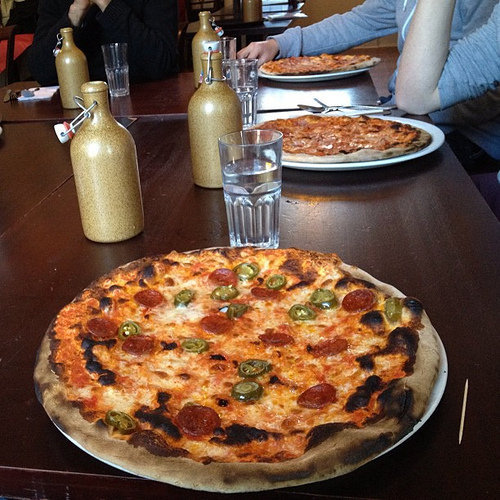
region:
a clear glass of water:
[214, 128, 284, 247]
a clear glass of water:
[224, 55, 259, 126]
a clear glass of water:
[214, 33, 237, 80]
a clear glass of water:
[98, 38, 130, 95]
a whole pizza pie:
[29, 245, 451, 492]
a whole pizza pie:
[246, 110, 443, 170]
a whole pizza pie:
[253, 53, 380, 78]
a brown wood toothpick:
[455, 377, 468, 444]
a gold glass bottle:
[51, 77, 146, 242]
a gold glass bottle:
[182, 39, 247, 189]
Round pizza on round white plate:
[31, 241, 443, 493]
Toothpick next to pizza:
[455, 378, 468, 446]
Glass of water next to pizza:
[217, 130, 283, 254]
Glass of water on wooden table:
[217, 130, 282, 245]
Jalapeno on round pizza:
[232, 380, 261, 402]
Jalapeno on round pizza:
[180, 335, 208, 353]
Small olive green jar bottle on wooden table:
[58, 80, 143, 242]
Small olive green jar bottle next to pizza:
[190, 41, 242, 188]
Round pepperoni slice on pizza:
[175, 402, 220, 437]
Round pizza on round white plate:
[250, 111, 431, 161]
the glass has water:
[221, 142, 278, 249]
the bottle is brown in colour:
[68, 85, 144, 239]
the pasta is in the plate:
[37, 242, 468, 497]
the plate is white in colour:
[430, 359, 447, 420]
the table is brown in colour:
[343, 198, 400, 232]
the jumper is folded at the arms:
[426, 43, 492, 110]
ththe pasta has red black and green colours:
[92, 242, 424, 494]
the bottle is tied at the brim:
[51, 88, 121, 155]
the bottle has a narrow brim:
[51, 25, 83, 50]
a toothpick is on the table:
[448, 375, 472, 442]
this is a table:
[386, 191, 461, 238]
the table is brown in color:
[330, 195, 420, 247]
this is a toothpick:
[452, 370, 474, 447]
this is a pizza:
[42, 248, 434, 464]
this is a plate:
[432, 395, 439, 406]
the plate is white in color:
[431, 384, 443, 397]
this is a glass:
[205, 130, 297, 247]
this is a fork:
[293, 93, 398, 113]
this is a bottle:
[55, 78, 156, 243]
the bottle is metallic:
[77, 155, 132, 208]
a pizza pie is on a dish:
[38, 237, 436, 493]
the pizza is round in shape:
[41, 237, 443, 481]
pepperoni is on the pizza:
[177, 405, 217, 434]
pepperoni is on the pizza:
[202, 313, 235, 334]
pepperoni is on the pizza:
[88, 314, 115, 343]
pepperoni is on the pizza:
[301, 380, 333, 407]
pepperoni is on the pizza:
[343, 288, 374, 311]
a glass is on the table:
[216, 127, 288, 248]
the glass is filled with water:
[210, 130, 293, 246]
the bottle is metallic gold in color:
[70, 78, 142, 244]